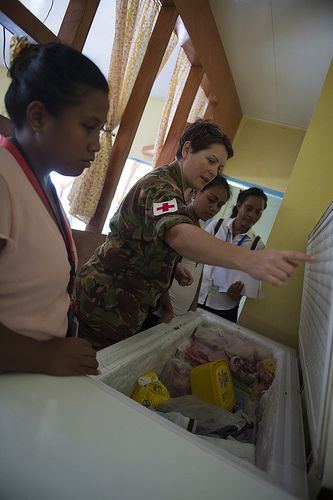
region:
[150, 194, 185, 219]
red cross on sleeve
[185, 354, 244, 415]
yellow container in freezer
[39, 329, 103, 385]
woman's hand on freezer edge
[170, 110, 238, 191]
woman with short hair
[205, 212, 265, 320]
woman wearing white shirt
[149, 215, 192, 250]
rolled up sleeve of shirt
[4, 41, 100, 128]
woman's black hair pulled back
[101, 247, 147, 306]
camouflage print on shirt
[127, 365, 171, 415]
yellow bag tied at top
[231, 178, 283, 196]
blue edge over doorway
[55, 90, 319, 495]
lady pointing at fridge door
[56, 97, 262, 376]
lady wearing army uniform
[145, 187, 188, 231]
lady has red cross on sleeve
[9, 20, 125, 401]
lady wearing pink shirt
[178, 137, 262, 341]
lady wearing white shirt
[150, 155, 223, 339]
lady wearing white shirt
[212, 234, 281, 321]
lady holding papers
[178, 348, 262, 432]
yellow container in fridge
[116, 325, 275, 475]
meat and supplies in freezer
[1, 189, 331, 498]
white deep freezer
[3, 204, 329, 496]
the freezer is in the open position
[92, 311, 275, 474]
the freezer has frost accumulated on the sides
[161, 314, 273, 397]
the meat is frozen in the freezer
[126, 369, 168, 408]
a frozen turkey is in the freezer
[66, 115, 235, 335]
the lady is wearing a camouflage uniform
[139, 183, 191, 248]
a red cross emblem is on the shoulder of the uniform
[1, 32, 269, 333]
four women are looking in the freezer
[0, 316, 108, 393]
a lady's right arm is resting on the freezer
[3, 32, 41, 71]
a yellow ribbon is in the lady's hair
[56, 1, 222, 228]
curtains are hanging in the windows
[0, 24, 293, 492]
four ladies looking into freezer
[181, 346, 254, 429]
yellow container in freezer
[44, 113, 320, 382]
lady pointing into freezer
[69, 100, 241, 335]
lady wearing army uniform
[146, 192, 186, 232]
red cross on woman's sleeve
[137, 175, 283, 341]
ladies wearing white shirts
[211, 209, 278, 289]
lady has back pack on back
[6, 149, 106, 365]
lady has badges hanging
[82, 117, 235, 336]
woman in military uniform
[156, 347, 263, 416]
food in freezer box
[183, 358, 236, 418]
yellow plastic container in freezer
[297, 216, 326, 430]
open door on freezer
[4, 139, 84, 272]
red and black ribbon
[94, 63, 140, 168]
tied curtains on window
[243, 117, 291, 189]
yellow wall above doorway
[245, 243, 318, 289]
pointing finger on hand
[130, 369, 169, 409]
yellow bag of food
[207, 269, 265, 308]
hand holding stack of papers